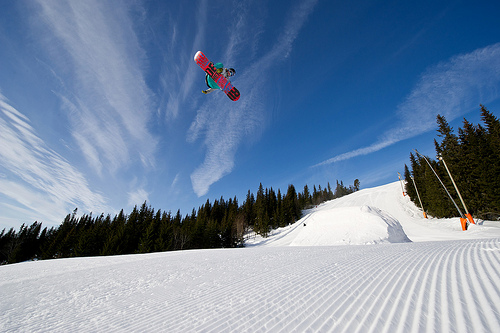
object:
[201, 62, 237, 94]
man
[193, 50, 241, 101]
snowboard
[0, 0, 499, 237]
clouds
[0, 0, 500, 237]
sky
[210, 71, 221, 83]
letters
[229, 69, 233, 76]
googles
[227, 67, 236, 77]
face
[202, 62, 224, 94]
pants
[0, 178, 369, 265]
trees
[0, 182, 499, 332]
snow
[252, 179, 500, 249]
ramp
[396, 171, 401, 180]
flag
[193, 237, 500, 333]
lines